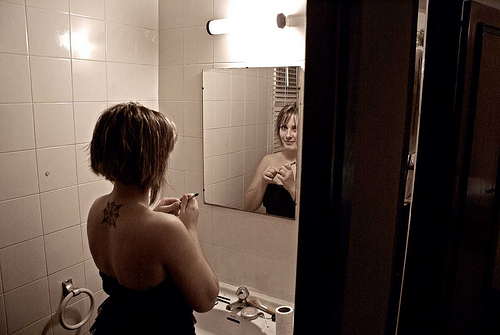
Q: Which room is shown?
A: It is a bathroom.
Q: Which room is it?
A: It is a bathroom.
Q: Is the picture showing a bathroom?
A: Yes, it is showing a bathroom.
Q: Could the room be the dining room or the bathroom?
A: It is the bathroom.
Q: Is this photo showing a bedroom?
A: No, the picture is showing a bathroom.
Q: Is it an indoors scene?
A: Yes, it is indoors.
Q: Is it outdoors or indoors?
A: It is indoors.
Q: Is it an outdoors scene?
A: No, it is indoors.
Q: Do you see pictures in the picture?
A: No, there are no pictures.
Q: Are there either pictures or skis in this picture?
A: No, there are no pictures or skis.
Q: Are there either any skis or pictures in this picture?
A: No, there are no pictures or skis.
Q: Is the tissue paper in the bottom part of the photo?
A: Yes, the tissue paper is in the bottom of the image.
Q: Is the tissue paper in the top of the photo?
A: No, the tissue paper is in the bottom of the image.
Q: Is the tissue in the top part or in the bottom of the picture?
A: The tissue is in the bottom of the image.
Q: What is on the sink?
A: The tissue is on the sink.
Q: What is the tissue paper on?
A: The tissue paper is on the sink.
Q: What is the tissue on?
A: The tissue paper is on the sink.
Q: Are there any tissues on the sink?
A: Yes, there is a tissue on the sink.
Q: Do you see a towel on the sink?
A: No, there is a tissue on the sink.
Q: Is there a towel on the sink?
A: No, there is a tissue on the sink.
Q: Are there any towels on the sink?
A: No, there is a tissue on the sink.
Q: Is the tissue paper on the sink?
A: Yes, the tissue paper is on the sink.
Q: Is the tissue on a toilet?
A: No, the tissue is on the sink.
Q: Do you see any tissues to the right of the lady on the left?
A: Yes, there is a tissue to the right of the lady.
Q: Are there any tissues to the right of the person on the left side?
A: Yes, there is a tissue to the right of the lady.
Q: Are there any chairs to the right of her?
A: No, there is a tissue to the right of the lady.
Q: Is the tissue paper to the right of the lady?
A: Yes, the tissue paper is to the right of the lady.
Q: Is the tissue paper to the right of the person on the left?
A: Yes, the tissue paper is to the right of the lady.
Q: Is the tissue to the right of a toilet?
A: No, the tissue is to the right of the lady.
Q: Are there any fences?
A: No, there are no fences.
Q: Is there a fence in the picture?
A: No, there are no fences.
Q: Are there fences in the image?
A: No, there are no fences.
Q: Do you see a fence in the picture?
A: No, there are no fences.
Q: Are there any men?
A: No, there are no men.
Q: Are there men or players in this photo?
A: No, there are no men or players.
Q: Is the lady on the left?
A: Yes, the lady is on the left of the image.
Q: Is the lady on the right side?
A: No, the lady is on the left of the image.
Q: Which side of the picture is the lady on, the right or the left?
A: The lady is on the left of the image.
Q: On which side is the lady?
A: The lady is on the left of the image.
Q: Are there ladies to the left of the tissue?
A: Yes, there is a lady to the left of the tissue.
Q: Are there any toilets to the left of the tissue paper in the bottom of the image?
A: No, there is a lady to the left of the tissue.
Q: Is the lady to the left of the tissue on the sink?
A: Yes, the lady is to the left of the tissue paper.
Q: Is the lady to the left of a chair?
A: No, the lady is to the left of the tissue paper.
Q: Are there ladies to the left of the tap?
A: Yes, there is a lady to the left of the tap.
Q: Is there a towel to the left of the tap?
A: No, there is a lady to the left of the tap.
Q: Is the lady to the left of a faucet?
A: Yes, the lady is to the left of a faucet.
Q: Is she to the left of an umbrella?
A: No, the lady is to the left of a faucet.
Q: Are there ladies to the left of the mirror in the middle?
A: Yes, there is a lady to the left of the mirror.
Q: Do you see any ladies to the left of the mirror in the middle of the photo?
A: Yes, there is a lady to the left of the mirror.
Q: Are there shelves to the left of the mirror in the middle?
A: No, there is a lady to the left of the mirror.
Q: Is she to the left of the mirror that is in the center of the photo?
A: Yes, the lady is to the left of the mirror.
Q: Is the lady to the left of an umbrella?
A: No, the lady is to the left of the mirror.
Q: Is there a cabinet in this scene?
A: No, there are no cabinets.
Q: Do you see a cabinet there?
A: No, there are no cabinets.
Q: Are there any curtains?
A: No, there are no curtains.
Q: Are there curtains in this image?
A: No, there are no curtains.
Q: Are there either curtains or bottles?
A: No, there are no curtains or bottles.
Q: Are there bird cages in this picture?
A: No, there are no bird cages.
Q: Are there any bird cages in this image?
A: No, there are no bird cages.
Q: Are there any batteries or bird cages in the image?
A: No, there are no bird cages or batteries.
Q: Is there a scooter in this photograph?
A: No, there are no scooters.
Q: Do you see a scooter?
A: No, there are no scooters.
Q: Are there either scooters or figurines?
A: No, there are no scooters or figurines.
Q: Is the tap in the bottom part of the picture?
A: Yes, the tap is in the bottom of the image.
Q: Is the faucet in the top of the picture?
A: No, the faucet is in the bottom of the image.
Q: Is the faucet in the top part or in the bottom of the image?
A: The faucet is in the bottom of the image.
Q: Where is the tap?
A: The tap is in the bathroom.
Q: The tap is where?
A: The tap is in the bathroom.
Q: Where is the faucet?
A: The tap is in the bathroom.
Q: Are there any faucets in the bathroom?
A: Yes, there is a faucet in the bathroom.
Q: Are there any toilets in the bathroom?
A: No, there is a faucet in the bathroom.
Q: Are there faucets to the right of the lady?
A: Yes, there is a faucet to the right of the lady.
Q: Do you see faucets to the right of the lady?
A: Yes, there is a faucet to the right of the lady.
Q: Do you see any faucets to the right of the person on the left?
A: Yes, there is a faucet to the right of the lady.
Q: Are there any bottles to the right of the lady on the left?
A: No, there is a faucet to the right of the lady.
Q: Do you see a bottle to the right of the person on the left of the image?
A: No, there is a faucet to the right of the lady.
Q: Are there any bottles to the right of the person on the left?
A: No, there is a faucet to the right of the lady.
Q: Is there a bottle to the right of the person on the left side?
A: No, there is a faucet to the right of the lady.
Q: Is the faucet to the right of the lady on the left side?
A: Yes, the faucet is to the right of the lady.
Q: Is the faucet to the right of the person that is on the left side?
A: Yes, the faucet is to the right of the lady.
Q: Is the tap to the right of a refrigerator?
A: No, the tap is to the right of the lady.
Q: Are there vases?
A: No, there are no vases.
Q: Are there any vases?
A: No, there are no vases.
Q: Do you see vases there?
A: No, there are no vases.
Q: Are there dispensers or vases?
A: No, there are no vases or dispensers.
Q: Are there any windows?
A: Yes, there is a window.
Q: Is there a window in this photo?
A: Yes, there is a window.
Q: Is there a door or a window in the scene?
A: Yes, there is a window.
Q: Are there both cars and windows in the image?
A: No, there is a window but no cars.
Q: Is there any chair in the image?
A: No, there are no chairs.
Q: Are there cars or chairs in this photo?
A: No, there are no chairs or cars.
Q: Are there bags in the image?
A: No, there are no bags.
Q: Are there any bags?
A: No, there are no bags.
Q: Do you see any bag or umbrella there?
A: No, there are no bags or umbrellas.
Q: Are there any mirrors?
A: Yes, there is a mirror.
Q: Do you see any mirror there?
A: Yes, there is a mirror.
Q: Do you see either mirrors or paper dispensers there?
A: Yes, there is a mirror.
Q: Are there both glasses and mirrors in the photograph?
A: No, there is a mirror but no glasses.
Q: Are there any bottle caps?
A: No, there are no bottle caps.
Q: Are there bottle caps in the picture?
A: No, there are no bottle caps.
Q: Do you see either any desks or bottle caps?
A: No, there are no bottle caps or desks.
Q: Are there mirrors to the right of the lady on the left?
A: Yes, there is a mirror to the right of the lady.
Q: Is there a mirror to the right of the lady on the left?
A: Yes, there is a mirror to the right of the lady.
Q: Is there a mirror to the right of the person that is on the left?
A: Yes, there is a mirror to the right of the lady.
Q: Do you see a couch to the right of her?
A: No, there is a mirror to the right of the lady.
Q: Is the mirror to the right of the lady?
A: Yes, the mirror is to the right of the lady.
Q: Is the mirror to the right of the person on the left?
A: Yes, the mirror is to the right of the lady.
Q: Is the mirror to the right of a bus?
A: No, the mirror is to the right of the lady.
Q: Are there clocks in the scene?
A: No, there are no clocks.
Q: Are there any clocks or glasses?
A: No, there are no clocks or glasses.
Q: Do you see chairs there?
A: No, there are no chairs.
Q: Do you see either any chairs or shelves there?
A: No, there are no chairs or shelves.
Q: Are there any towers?
A: No, there are no towers.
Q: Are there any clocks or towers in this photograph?
A: No, there are no towers or clocks.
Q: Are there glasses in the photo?
A: No, there are no glasses.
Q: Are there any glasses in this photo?
A: No, there are no glasses.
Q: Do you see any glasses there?
A: No, there are no glasses.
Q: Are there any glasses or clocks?
A: No, there are no glasses or clocks.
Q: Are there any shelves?
A: No, there are no shelves.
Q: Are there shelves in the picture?
A: No, there are no shelves.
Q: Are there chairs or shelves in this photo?
A: No, there are no shelves or chairs.